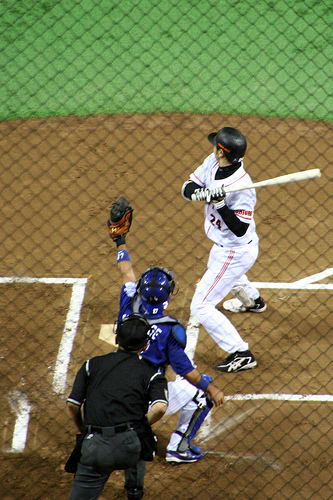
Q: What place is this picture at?
A: It is at the field.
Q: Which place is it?
A: It is a field.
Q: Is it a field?
A: Yes, it is a field.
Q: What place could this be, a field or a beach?
A: It is a field.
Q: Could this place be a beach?
A: No, it is a field.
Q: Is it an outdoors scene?
A: Yes, it is outdoors.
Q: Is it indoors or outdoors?
A: It is outdoors.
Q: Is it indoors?
A: No, it is outdoors.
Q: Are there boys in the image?
A: No, there are no boys.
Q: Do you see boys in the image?
A: No, there are no boys.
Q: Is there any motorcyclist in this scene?
A: No, there are no bikers.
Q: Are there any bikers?
A: No, there are no bikers.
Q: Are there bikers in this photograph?
A: No, there are no bikers.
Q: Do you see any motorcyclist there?
A: No, there are no bikers.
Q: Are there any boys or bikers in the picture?
A: No, there are no bikers or boys.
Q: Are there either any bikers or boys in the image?
A: No, there are no bikers or boys.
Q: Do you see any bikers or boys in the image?
A: No, there are no bikers or boys.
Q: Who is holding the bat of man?
A: The man is holding the bat.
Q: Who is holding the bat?
A: The man is holding the bat.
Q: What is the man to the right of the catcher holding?
A: The man is holding the bat.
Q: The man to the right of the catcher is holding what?
A: The man is holding the bat.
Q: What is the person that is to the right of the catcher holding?
A: The man is holding the bat.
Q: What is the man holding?
A: The man is holding the bat.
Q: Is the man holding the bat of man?
A: Yes, the man is holding the bat.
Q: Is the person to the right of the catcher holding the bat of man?
A: Yes, the man is holding the bat.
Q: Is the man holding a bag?
A: No, the man is holding the bat.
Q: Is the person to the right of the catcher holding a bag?
A: No, the man is holding the bat.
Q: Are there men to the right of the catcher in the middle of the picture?
A: Yes, there is a man to the right of the catcher.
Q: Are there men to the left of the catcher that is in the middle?
A: No, the man is to the right of the catcher.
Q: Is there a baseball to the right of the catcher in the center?
A: No, there is a man to the right of the catcher.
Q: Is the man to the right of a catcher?
A: Yes, the man is to the right of a catcher.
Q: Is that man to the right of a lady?
A: No, the man is to the right of a catcher.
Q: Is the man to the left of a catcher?
A: No, the man is to the right of a catcher.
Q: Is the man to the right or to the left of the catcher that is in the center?
A: The man is to the right of the catcher.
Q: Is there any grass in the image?
A: Yes, there is grass.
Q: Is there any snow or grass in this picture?
A: Yes, there is grass.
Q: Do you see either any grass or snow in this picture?
A: Yes, there is grass.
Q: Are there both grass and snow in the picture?
A: No, there is grass but no snow.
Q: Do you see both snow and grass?
A: No, there is grass but no snow.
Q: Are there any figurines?
A: No, there are no figurines.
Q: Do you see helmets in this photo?
A: Yes, there is a helmet.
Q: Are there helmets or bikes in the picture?
A: Yes, there is a helmet.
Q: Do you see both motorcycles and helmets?
A: No, there is a helmet but no motorcycles.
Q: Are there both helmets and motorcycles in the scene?
A: No, there is a helmet but no motorcycles.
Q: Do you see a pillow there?
A: No, there are no pillows.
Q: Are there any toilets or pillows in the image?
A: No, there are no pillows or toilets.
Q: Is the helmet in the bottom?
A: No, the helmet is in the top of the image.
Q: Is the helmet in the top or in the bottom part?
A: The helmet is in the top of the image.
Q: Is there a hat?
A: Yes, there is a hat.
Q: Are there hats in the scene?
A: Yes, there is a hat.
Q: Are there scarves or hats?
A: Yes, there is a hat.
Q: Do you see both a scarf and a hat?
A: No, there is a hat but no scarves.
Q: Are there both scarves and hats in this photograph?
A: No, there is a hat but no scarves.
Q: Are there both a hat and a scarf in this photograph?
A: No, there is a hat but no scarves.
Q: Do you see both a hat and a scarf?
A: No, there is a hat but no scarves.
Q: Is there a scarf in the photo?
A: No, there are no scarves.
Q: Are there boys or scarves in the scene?
A: No, there are no scarves or boys.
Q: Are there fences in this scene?
A: Yes, there is a fence.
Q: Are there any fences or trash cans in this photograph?
A: Yes, there is a fence.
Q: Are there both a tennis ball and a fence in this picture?
A: No, there is a fence but no tennis balls.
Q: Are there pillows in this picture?
A: No, there are no pillows.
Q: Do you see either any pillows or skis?
A: No, there are no pillows or skis.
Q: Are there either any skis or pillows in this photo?
A: No, there are no pillows or skis.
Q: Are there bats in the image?
A: Yes, there is a bat.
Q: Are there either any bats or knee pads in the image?
A: Yes, there is a bat.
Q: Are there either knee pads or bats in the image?
A: Yes, there is a bat.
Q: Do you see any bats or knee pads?
A: Yes, there is a bat.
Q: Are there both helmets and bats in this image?
A: Yes, there are both a bat and a helmet.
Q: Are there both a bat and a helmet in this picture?
A: Yes, there are both a bat and a helmet.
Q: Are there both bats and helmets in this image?
A: Yes, there are both a bat and a helmet.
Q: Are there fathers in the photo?
A: No, there are no fathers.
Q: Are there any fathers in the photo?
A: No, there are no fathers.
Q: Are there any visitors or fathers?
A: No, there are no fathers or visitors.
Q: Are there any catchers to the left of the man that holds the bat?
A: Yes, there is a catcher to the left of the man.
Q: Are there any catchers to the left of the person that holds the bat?
A: Yes, there is a catcher to the left of the man.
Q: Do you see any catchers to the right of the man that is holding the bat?
A: No, the catcher is to the left of the man.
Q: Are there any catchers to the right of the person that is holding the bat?
A: No, the catcher is to the left of the man.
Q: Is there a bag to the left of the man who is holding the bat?
A: No, there is a catcher to the left of the man.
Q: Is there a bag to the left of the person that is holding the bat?
A: No, there is a catcher to the left of the man.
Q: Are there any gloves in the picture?
A: Yes, there are gloves.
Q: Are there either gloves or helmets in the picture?
A: Yes, there are gloves.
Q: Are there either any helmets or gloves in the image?
A: Yes, there are gloves.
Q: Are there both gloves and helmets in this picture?
A: Yes, there are both gloves and a helmet.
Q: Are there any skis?
A: No, there are no skis.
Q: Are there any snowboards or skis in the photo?
A: No, there are no skis or snowboards.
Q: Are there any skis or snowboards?
A: No, there are no skis or snowboards.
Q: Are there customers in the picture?
A: No, there are no customers.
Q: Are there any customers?
A: No, there are no customers.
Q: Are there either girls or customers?
A: No, there are no customers or girls.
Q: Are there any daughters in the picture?
A: No, there are no daughters.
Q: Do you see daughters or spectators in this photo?
A: No, there are no daughters or spectators.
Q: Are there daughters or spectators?
A: No, there are no daughters or spectators.